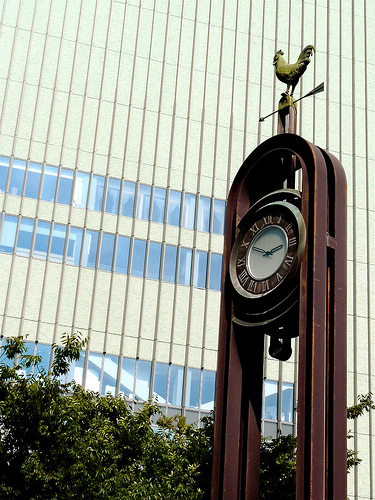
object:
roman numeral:
[289, 237, 296, 248]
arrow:
[258, 81, 324, 122]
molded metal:
[259, 44, 324, 122]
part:
[269, 323, 292, 361]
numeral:
[249, 223, 260, 236]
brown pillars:
[210, 133, 347, 500]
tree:
[10, 388, 214, 493]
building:
[2, 10, 216, 448]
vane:
[265, 431, 290, 491]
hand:
[252, 246, 269, 256]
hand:
[266, 244, 284, 256]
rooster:
[272, 44, 316, 97]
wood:
[137, 425, 186, 457]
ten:
[240, 240, 249, 249]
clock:
[228, 199, 306, 299]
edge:
[198, 368, 203, 411]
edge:
[181, 364, 188, 409]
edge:
[165, 364, 171, 405]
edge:
[148, 360, 155, 403]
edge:
[133, 357, 139, 398]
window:
[201, 370, 217, 411]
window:
[185, 365, 200, 410]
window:
[169, 364, 184, 408]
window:
[120, 356, 136, 400]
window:
[134, 359, 152, 403]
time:
[250, 227, 284, 267]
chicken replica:
[273, 44, 316, 96]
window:
[0, 150, 29, 198]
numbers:
[237, 256, 247, 283]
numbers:
[263, 214, 282, 225]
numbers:
[285, 236, 298, 266]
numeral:
[241, 240, 250, 249]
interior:
[247, 249, 274, 274]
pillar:
[297, 306, 348, 498]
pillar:
[211, 320, 266, 499]